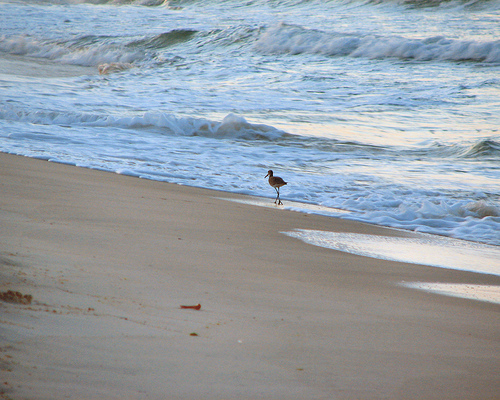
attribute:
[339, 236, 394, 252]
sand — wet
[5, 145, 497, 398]
beach — grey, flat, sandy